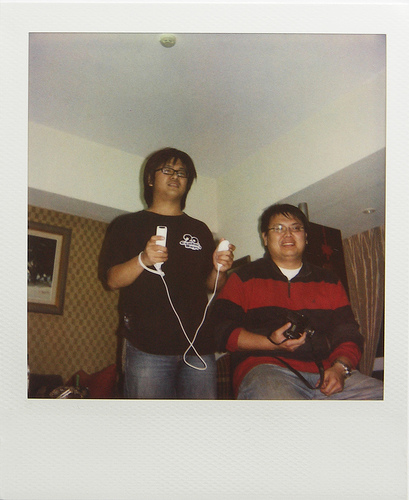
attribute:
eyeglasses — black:
[146, 167, 217, 188]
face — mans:
[153, 160, 214, 209]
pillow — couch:
[65, 364, 119, 396]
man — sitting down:
[219, 189, 390, 399]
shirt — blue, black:
[96, 209, 215, 355]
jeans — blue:
[121, 340, 385, 400]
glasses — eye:
[262, 222, 305, 232]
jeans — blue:
[118, 341, 213, 395]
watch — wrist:
[331, 354, 356, 374]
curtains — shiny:
[336, 243, 399, 330]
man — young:
[226, 199, 385, 398]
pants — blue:
[236, 352, 380, 398]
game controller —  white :
[153, 226, 168, 265]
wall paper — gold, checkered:
[27, 205, 124, 375]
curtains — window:
[346, 224, 382, 361]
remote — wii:
[143, 218, 177, 276]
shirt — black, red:
[207, 248, 365, 385]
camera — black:
[266, 310, 327, 391]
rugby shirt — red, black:
[212, 262, 363, 369]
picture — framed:
[26, 216, 75, 318]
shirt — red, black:
[209, 256, 365, 391]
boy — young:
[94, 148, 218, 394]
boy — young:
[202, 204, 376, 397]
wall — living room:
[32, 201, 182, 401]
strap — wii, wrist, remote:
[131, 243, 167, 280]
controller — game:
[138, 215, 232, 373]